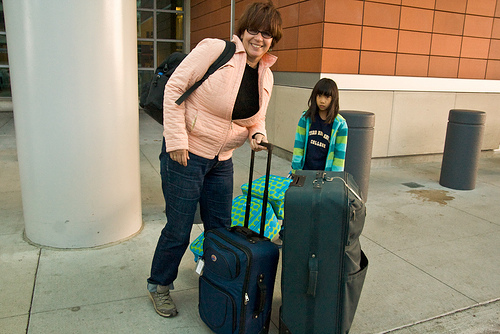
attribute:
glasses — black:
[242, 22, 275, 39]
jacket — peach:
[163, 42, 275, 164]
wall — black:
[323, 0, 498, 84]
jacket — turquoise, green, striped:
[290, 112, 347, 174]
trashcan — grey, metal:
[437, 97, 492, 189]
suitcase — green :
[277, 161, 369, 331]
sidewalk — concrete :
[1, 155, 498, 332]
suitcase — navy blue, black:
[198, 145, 278, 330]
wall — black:
[319, 6, 461, 78]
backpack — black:
[142, 50, 181, 116]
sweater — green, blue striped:
[262, 115, 397, 178]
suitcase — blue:
[198, 224, 279, 332]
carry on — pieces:
[196, 133, 285, 324]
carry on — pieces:
[279, 154, 359, 316]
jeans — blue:
[145, 174, 292, 318]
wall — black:
[365, 51, 429, 130]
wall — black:
[382, 50, 453, 82]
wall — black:
[427, 50, 453, 130]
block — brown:
[319, 20, 364, 53]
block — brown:
[359, 21, 401, 54]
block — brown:
[395, 28, 432, 57]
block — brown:
[357, 49, 397, 76]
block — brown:
[393, 50, 431, 76]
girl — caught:
[288, 76, 347, 173]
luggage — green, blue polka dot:
[198, 135, 279, 332]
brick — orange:
[319, 19, 362, 50]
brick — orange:
[318, 45, 361, 74]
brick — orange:
[357, 47, 397, 77]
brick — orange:
[359, 24, 400, 53]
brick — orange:
[394, 25, 433, 56]